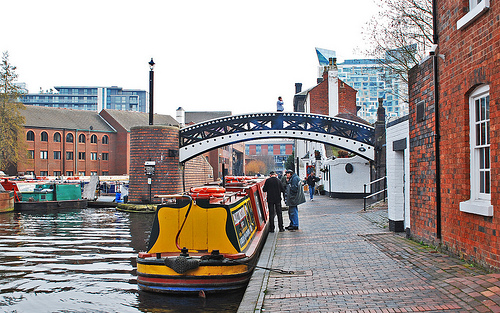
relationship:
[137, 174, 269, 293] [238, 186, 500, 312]
boats beside walkway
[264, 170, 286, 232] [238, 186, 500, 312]
person on walkway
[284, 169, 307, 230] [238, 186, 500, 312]
person on walkway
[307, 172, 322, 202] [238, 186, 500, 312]
person on walkway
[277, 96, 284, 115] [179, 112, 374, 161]
person on overpass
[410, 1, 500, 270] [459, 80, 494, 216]
building has window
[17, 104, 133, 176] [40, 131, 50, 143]
building has window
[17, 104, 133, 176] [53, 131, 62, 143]
building has window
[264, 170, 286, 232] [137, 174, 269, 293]
person boarding boats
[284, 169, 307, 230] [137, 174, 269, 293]
person boarding boats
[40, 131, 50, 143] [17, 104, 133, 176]
window on building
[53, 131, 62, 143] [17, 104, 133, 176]
window on building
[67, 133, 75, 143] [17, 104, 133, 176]
window on building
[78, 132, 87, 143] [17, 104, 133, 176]
window on building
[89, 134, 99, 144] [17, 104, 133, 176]
window on building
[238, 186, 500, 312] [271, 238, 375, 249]
walkway has lines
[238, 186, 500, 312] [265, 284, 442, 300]
walkway has lines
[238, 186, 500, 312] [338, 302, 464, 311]
walkway has lines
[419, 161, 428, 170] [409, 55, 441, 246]
bricks on wall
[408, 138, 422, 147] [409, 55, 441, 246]
bricks on wall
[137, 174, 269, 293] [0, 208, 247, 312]
boats in water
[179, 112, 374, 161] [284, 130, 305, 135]
overpass has spots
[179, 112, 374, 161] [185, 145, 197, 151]
overpass has spots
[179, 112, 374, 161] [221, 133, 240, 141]
overpass has spots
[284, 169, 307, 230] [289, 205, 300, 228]
person wearing jeans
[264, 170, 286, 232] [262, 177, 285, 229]
person wearing clothes